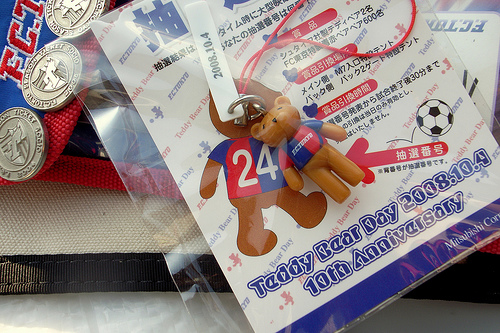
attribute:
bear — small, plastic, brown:
[243, 107, 371, 202]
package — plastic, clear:
[44, 0, 500, 314]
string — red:
[236, 0, 418, 93]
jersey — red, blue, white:
[277, 117, 324, 168]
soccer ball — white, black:
[416, 98, 452, 136]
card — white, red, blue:
[90, 1, 498, 332]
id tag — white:
[186, 4, 248, 125]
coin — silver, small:
[1, 107, 47, 182]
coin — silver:
[13, 42, 91, 111]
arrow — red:
[342, 137, 450, 184]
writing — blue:
[243, 147, 495, 307]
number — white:
[225, 144, 279, 189]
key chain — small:
[228, 95, 266, 126]